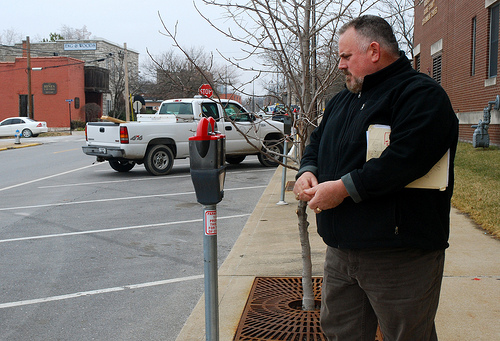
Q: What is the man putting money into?
A: Meter.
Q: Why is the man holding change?
A: Parking meter.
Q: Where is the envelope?
A: Under arm.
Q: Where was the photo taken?
A: Parking lot.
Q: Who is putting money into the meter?
A: Large man.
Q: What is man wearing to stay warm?
A: Black coat.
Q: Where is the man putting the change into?
A: Meter.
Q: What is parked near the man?
A: White truck.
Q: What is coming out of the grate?
A: Tree.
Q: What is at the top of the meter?
A: Coin drop.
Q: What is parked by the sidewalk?
A: Truck.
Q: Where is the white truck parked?
A: Sidewalk.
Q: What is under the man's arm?
A: File folder.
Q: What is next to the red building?
A: Car.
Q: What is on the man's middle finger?
A: Ring.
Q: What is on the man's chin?
A: Beard.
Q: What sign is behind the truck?
A: Stop sign.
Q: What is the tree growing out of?
A: Grate.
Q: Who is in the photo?
A: The man.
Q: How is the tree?
A: Bare.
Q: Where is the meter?
A: Pole.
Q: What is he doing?
A: Paying meter.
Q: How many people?
A: 1.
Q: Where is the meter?
A: In Front of the guy.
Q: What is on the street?
A: Strips.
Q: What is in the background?
A: Buildings.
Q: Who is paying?
A: The guy.